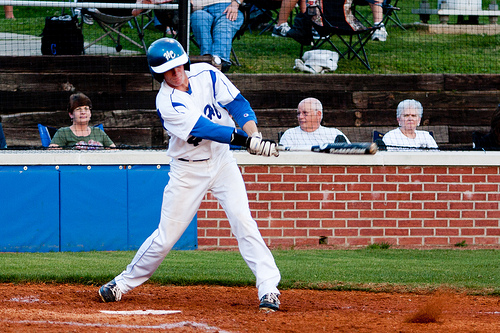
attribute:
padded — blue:
[1, 161, 193, 254]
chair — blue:
[36, 119, 108, 146]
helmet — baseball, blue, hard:
[143, 36, 188, 73]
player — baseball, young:
[97, 35, 280, 312]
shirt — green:
[288, 132, 331, 154]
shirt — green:
[157, 86, 200, 128]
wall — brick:
[406, 115, 451, 155]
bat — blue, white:
[273, 133, 377, 156]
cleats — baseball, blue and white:
[67, 267, 141, 328]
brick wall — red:
[195, 161, 500, 249]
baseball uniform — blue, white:
[114, 60, 281, 302]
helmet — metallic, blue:
[139, 33, 184, 80]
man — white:
[100, 42, 287, 307]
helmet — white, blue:
[140, 32, 200, 77]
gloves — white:
[246, 133, 282, 158]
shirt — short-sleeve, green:
[51, 124, 111, 147]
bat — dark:
[280, 141, 384, 161]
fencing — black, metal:
[208, 7, 498, 82]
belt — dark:
[171, 149, 212, 163]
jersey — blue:
[150, 65, 262, 154]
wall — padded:
[4, 165, 202, 254]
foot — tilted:
[93, 264, 129, 305]